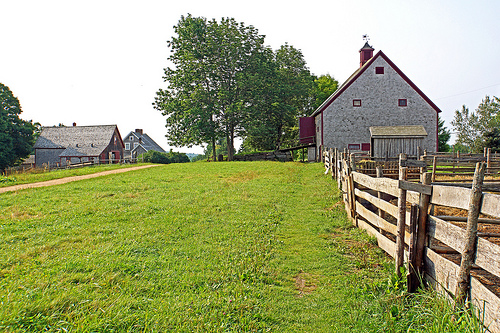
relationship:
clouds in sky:
[0, 0, 499, 155] [410, 0, 498, 144]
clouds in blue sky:
[0, 0, 499, 155] [391, 5, 496, 94]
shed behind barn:
[359, 117, 439, 169] [310, 41, 441, 160]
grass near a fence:
[0, 160, 499, 332] [325, 154, 498, 290]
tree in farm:
[0, 83, 33, 177] [0, 162, 498, 332]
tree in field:
[156, 11, 278, 162] [4, 145, 456, 330]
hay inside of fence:
[415, 172, 499, 246] [320, 146, 497, 331]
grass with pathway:
[0, 159, 333, 331] [0, 164, 161, 196]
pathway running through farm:
[0, 163, 165, 190] [0, 162, 498, 332]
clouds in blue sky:
[340, 13, 484, 71] [0, 0, 499, 155]